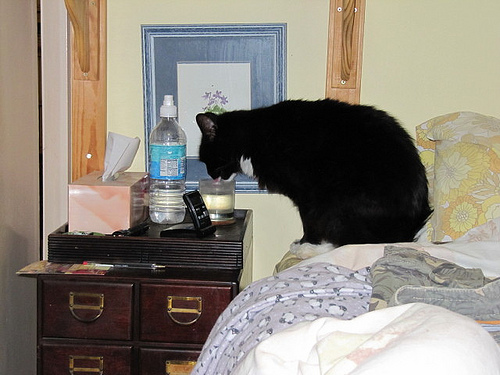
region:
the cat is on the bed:
[170, 76, 455, 265]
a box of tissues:
[48, 117, 161, 230]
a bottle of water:
[138, 70, 201, 232]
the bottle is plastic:
[127, 63, 208, 235]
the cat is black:
[171, 67, 441, 253]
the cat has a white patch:
[162, 75, 428, 242]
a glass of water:
[190, 161, 257, 228]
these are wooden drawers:
[15, 271, 275, 373]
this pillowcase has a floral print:
[413, 102, 498, 251]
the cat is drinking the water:
[160, 95, 459, 261]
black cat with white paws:
[194, 98, 435, 257]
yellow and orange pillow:
[417, 110, 498, 243]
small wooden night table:
[36, 274, 259, 372]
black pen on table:
[76, 256, 170, 274]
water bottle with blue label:
[149, 90, 186, 226]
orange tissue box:
[70, 171, 147, 234]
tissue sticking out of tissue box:
[69, 131, 146, 234]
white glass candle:
[195, 182, 235, 217]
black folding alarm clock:
[154, 188, 220, 236]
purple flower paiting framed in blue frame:
[141, 21, 286, 192]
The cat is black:
[192, 93, 432, 252]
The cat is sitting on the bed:
[196, 89, 448, 283]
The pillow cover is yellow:
[424, 95, 497, 262]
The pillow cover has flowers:
[432, 148, 474, 196]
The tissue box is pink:
[49, 140, 141, 240]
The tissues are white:
[93, 113, 136, 193]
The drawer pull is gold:
[59, 289, 112, 323]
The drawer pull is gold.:
[159, 290, 205, 328]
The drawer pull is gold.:
[57, 350, 112, 374]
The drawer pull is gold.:
[155, 357, 200, 374]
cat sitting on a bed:
[28, 16, 468, 357]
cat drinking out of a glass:
[192, 103, 442, 245]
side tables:
[28, 215, 249, 373]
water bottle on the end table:
[146, 82, 186, 238]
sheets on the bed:
[207, 222, 497, 367]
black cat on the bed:
[193, 98, 426, 248]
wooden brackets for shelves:
[311, 2, 371, 107]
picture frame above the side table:
[135, 10, 296, 198]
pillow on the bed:
[417, 95, 497, 240]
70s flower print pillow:
[415, 109, 499, 246]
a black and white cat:
[195, 92, 443, 267]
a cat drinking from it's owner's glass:
[156, 93, 438, 288]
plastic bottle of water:
[143, 86, 192, 228]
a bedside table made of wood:
[13, 183, 263, 372]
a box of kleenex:
[61, 118, 148, 235]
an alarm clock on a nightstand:
[20, 183, 263, 373]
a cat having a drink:
[137, 10, 457, 305]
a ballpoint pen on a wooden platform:
[61, 251, 178, 273]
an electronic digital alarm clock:
[151, 187, 223, 244]